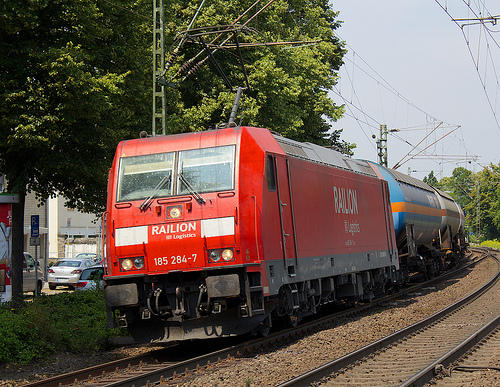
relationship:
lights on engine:
[106, 223, 261, 278] [123, 132, 455, 294]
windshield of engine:
[112, 140, 240, 203] [102, 126, 402, 345]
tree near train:
[1, 2, 354, 223] [100, 123, 471, 349]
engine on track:
[102, 126, 402, 345] [438, 246, 500, 333]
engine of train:
[102, 126, 402, 345] [100, 123, 471, 349]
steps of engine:
[269, 155, 300, 318] [102, 126, 402, 345]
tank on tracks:
[361, 157, 443, 249] [1, 245, 496, 383]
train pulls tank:
[102, 125, 470, 347] [353, 159, 472, 282]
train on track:
[112, 119, 400, 333] [1, 244, 490, 384]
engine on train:
[102, 126, 402, 345] [100, 123, 471, 349]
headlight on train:
[223, 243, 237, 260] [100, 123, 471, 349]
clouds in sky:
[355, 10, 498, 180] [317, 4, 498, 196]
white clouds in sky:
[468, 115, 487, 133] [317, 4, 498, 196]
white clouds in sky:
[440, 84, 463, 108] [317, 4, 498, 196]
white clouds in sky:
[405, 37, 440, 62] [317, 4, 498, 196]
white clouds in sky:
[360, 90, 387, 105] [317, 4, 498, 196]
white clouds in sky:
[373, 26, 395, 51] [317, 4, 498, 196]